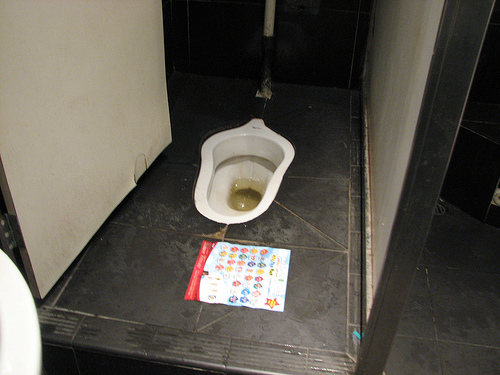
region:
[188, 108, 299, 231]
a toilet is dirty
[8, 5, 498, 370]
a soiled toilet in a bathroom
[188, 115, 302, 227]
a white toilet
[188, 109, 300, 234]
toilet without lid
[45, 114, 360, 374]
floor of toilet is black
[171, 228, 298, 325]
a colorful paper on floor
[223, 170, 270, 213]
brown water on toilet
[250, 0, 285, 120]
tube over the toilet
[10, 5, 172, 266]
white wall on side of toilet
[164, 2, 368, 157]
black wall on back of toilet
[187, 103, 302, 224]
a toilet in the floor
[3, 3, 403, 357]
restroom cubicle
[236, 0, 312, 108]
a black and white pipe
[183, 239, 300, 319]
poster on the floor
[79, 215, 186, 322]
black tiled flooring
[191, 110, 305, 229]
a dirty white toilet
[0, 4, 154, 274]
white wall partition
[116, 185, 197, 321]
dirty tiled flooring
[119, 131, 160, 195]
a dent in the white partition wall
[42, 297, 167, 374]
a step up into the toilet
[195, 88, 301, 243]
urinal on the floor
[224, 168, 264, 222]
water in the urinal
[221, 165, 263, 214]
the water is yellow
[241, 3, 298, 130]
pipe connected to urinal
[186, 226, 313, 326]
paper in front of urinal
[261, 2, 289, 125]
pipe is white and black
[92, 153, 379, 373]
the floor is black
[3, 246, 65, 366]
white object in left corner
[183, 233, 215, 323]
bottom of page is red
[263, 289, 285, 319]
star on the page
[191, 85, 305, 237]
dirty urinal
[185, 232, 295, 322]
sheet of stickers on the floor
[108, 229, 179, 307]
black tile bathroom floor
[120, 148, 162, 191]
hole in sheetrock wall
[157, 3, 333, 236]
older style toilet that needs to be cleaned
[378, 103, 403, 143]
white painted wall in bathroom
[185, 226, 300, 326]
reward stickers on sheet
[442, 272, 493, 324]
dust-covered black floor tiles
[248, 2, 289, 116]
exposed water pipe coming down from ceiling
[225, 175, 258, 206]
filthy colored water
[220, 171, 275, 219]
dirty water in the toilet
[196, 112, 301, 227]
a white urinal in the ground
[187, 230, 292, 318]
a white sticker sheet on the ground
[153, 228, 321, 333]
a piece of paper on the ground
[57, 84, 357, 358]
black tiled floor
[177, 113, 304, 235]
dirty toilet seat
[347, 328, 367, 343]
blue garbage on the floor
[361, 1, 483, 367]
a dividing wall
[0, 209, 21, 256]
black hinges on a door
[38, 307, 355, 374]
step up